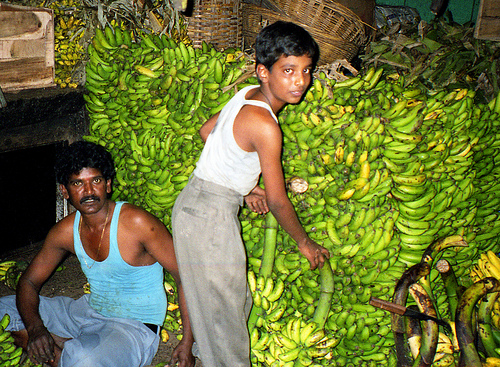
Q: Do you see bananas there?
A: Yes, there are bananas.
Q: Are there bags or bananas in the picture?
A: Yes, there are bananas.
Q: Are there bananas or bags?
A: Yes, there are bananas.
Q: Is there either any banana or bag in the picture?
A: Yes, there are bananas.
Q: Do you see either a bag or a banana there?
A: Yes, there are bananas.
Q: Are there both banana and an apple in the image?
A: No, there are bananas but no apples.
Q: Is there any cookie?
A: No, there are no cookies.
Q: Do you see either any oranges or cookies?
A: No, there are no cookies or oranges.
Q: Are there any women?
A: No, there are no women.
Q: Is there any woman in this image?
A: No, there are no women.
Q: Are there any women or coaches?
A: No, there are no women or coaches.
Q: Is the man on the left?
A: Yes, the man is on the left of the image.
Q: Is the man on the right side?
A: No, the man is on the left of the image.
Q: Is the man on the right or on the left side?
A: The man is on the left of the image.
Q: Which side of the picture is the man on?
A: The man is on the left of the image.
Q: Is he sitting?
A: Yes, the man is sitting.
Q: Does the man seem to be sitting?
A: Yes, the man is sitting.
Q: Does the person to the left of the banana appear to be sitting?
A: Yes, the man is sitting.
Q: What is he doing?
A: The man is sitting.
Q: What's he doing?
A: The man is sitting.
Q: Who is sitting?
A: The man is sitting.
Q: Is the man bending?
A: No, the man is sitting.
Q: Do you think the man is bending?
A: No, the man is sitting.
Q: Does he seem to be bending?
A: No, the man is sitting.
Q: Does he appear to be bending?
A: No, the man is sitting.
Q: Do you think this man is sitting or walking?
A: The man is sitting.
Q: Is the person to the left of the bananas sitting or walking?
A: The man is sitting.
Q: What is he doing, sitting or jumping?
A: The man is sitting.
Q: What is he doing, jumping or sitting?
A: The man is sitting.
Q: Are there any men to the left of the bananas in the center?
A: Yes, there is a man to the left of the bananas.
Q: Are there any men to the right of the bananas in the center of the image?
A: No, the man is to the left of the bananas.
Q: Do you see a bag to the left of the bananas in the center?
A: No, there is a man to the left of the bananas.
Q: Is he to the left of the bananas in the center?
A: Yes, the man is to the left of the bananas.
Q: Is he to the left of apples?
A: No, the man is to the left of the bananas.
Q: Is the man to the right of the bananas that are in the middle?
A: No, the man is to the left of the bananas.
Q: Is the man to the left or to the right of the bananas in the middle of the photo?
A: The man is to the left of the bananas.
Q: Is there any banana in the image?
A: Yes, there are bananas.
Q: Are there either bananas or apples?
A: Yes, there are bananas.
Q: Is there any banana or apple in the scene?
A: Yes, there are bananas.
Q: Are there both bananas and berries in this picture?
A: No, there are bananas but no berries.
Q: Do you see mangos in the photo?
A: No, there are no mangos.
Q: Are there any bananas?
A: Yes, there are bananas.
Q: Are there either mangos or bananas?
A: Yes, there are bananas.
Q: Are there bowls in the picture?
A: No, there are no bowls.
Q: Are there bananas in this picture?
A: Yes, there are bananas.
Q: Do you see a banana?
A: Yes, there are bananas.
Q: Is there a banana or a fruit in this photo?
A: Yes, there are bananas.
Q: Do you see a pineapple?
A: No, there are no pineapples.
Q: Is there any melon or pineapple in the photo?
A: No, there are no pineapples or melons.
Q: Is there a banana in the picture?
A: Yes, there are bananas.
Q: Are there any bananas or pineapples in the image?
A: Yes, there are bananas.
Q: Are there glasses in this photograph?
A: No, there are no glasses.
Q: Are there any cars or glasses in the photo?
A: No, there are no glasses or cars.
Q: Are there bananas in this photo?
A: Yes, there are bananas.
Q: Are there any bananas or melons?
A: Yes, there are bananas.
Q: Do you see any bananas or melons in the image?
A: Yes, there are bananas.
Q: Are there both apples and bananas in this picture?
A: No, there are bananas but no apples.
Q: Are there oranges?
A: No, there are no oranges.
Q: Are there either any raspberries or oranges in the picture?
A: No, there are no oranges or raspberries.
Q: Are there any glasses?
A: No, there are no glasses.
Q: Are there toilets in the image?
A: No, there are no toilets.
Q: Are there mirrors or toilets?
A: No, there are no toilets or mirrors.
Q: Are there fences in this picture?
A: No, there are no fences.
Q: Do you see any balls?
A: No, there are no balls.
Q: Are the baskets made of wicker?
A: Yes, the baskets are made of wicker.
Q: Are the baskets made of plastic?
A: No, the baskets are made of wicker.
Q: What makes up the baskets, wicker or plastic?
A: The baskets are made of wicker.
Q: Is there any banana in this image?
A: Yes, there is a banana.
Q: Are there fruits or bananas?
A: Yes, there is a banana.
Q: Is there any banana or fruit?
A: Yes, there is a banana.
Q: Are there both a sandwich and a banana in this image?
A: No, there is a banana but no sandwiches.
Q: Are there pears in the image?
A: No, there are no pears.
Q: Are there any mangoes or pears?
A: No, there are no pears or mangoes.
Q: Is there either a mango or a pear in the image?
A: No, there are no pears or mangoes.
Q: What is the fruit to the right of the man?
A: The fruit is a banana.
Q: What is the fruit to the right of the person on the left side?
A: The fruit is a banana.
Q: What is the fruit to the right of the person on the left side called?
A: The fruit is a banana.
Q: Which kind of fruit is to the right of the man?
A: The fruit is a banana.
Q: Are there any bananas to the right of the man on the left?
A: Yes, there is a banana to the right of the man.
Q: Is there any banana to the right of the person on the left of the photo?
A: Yes, there is a banana to the right of the man.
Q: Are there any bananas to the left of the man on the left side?
A: No, the banana is to the right of the man.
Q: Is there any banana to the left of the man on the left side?
A: No, the banana is to the right of the man.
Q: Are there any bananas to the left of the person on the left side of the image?
A: No, the banana is to the right of the man.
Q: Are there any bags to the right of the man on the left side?
A: No, there is a banana to the right of the man.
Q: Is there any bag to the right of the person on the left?
A: No, there is a banana to the right of the man.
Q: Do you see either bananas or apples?
A: Yes, there are bananas.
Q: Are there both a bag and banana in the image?
A: No, there are bananas but no bags.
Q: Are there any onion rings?
A: No, there are no onion rings.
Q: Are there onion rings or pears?
A: No, there are no onion rings or pears.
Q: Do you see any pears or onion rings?
A: No, there are no onion rings or pears.